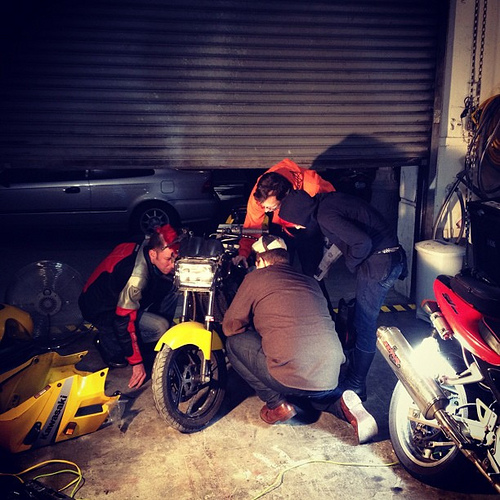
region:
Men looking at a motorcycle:
[17, 117, 490, 482]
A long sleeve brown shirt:
[230, 257, 350, 397]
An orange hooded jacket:
[238, 140, 328, 222]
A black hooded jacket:
[276, 187, 398, 267]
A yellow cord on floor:
[41, 446, 392, 499]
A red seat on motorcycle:
[418, 271, 498, 355]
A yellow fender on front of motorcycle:
[151, 317, 221, 362]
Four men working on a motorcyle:
[126, 162, 400, 354]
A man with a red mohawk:
[144, 219, 191, 253]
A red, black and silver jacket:
[81, 243, 153, 344]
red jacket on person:
[260, 157, 315, 194]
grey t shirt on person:
[239, 275, 344, 384]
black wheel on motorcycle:
[132, 325, 232, 437]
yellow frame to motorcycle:
[153, 317, 219, 354]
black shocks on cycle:
[178, 286, 217, 321]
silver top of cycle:
[151, 252, 241, 290]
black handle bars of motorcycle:
[209, 223, 270, 242]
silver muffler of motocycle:
[371, 320, 445, 419]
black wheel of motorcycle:
[390, 395, 465, 472]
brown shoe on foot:
[247, 398, 294, 422]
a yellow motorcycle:
[150, 217, 238, 436]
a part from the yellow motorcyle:
[2, 350, 122, 457]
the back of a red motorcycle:
[372, 267, 499, 494]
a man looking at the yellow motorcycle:
[79, 218, 182, 390]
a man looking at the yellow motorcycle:
[212, 232, 390, 448]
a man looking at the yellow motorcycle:
[277, 183, 406, 396]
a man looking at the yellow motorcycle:
[240, 152, 333, 264]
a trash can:
[413, 230, 465, 325]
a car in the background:
[1, 168, 226, 233]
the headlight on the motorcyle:
[174, 256, 219, 296]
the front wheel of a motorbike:
[151, 309, 228, 439]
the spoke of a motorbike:
[166, 360, 213, 396]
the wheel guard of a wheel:
[158, 300, 209, 353]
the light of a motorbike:
[160, 252, 222, 295]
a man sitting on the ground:
[226, 242, 376, 448]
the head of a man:
[233, 237, 298, 273]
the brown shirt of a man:
[226, 272, 357, 394]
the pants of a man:
[213, 300, 329, 413]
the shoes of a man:
[252, 390, 374, 443]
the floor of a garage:
[175, 431, 269, 495]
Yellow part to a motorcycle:
[2, 350, 135, 454]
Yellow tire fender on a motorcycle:
[150, 322, 228, 434]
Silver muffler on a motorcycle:
[369, 313, 436, 451]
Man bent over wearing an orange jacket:
[235, 159, 334, 250]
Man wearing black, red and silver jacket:
[77, 224, 184, 386]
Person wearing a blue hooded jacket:
[277, 183, 413, 260]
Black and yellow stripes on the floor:
[382, 303, 419, 311]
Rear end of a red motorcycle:
[373, 268, 498, 497]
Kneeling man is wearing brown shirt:
[220, 262, 353, 401]